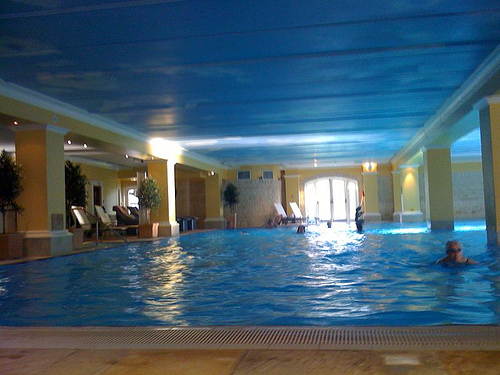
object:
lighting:
[13, 120, 18, 125]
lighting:
[82, 143, 88, 149]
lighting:
[125, 154, 129, 159]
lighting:
[67, 140, 72, 145]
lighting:
[211, 171, 215, 176]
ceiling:
[0, 0, 499, 168]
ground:
[355, 205, 365, 231]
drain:
[0, 313, 500, 351]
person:
[435, 241, 477, 265]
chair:
[70, 195, 141, 238]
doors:
[299, 173, 358, 222]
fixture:
[403, 166, 414, 181]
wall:
[0, 92, 500, 263]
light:
[138, 233, 197, 328]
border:
[0, 327, 499, 374]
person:
[327, 221, 331, 227]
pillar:
[478, 103, 498, 245]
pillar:
[363, 170, 381, 223]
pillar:
[283, 170, 300, 216]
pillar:
[420, 147, 454, 230]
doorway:
[92, 185, 104, 218]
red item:
[362, 191, 364, 197]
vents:
[238, 171, 251, 180]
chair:
[288, 201, 309, 223]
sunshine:
[293, 189, 369, 255]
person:
[296, 225, 305, 233]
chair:
[112, 205, 140, 235]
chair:
[272, 201, 290, 230]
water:
[49, 241, 442, 319]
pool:
[0, 221, 500, 326]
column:
[138, 160, 180, 238]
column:
[10, 127, 74, 258]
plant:
[0, 149, 26, 217]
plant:
[64, 159, 89, 228]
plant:
[137, 177, 163, 224]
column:
[204, 175, 227, 230]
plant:
[221, 182, 241, 214]